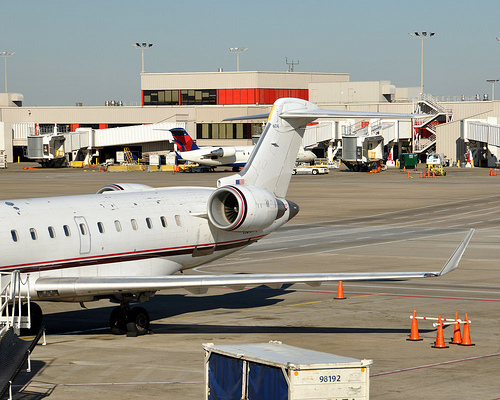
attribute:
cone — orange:
[408, 308, 423, 342]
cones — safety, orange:
[332, 279, 476, 347]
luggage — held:
[209, 358, 290, 399]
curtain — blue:
[207, 352, 290, 399]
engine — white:
[205, 185, 285, 230]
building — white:
[0, 72, 498, 166]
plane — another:
[164, 123, 318, 174]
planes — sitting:
[2, 97, 476, 329]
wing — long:
[16, 228, 473, 299]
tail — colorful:
[171, 125, 202, 153]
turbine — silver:
[221, 193, 244, 226]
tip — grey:
[274, 201, 289, 219]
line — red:
[0, 236, 264, 278]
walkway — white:
[69, 118, 189, 150]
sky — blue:
[1, 2, 499, 105]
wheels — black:
[108, 305, 150, 338]